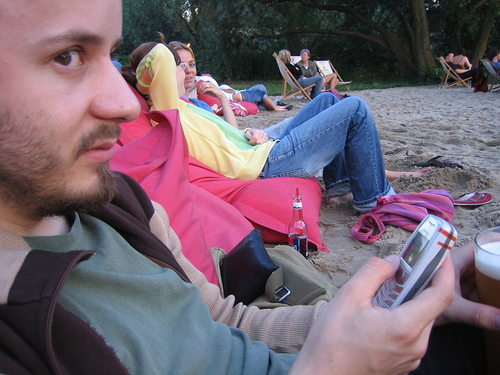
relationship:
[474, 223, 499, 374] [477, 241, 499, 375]
glass for drinking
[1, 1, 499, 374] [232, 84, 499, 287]
people are at beach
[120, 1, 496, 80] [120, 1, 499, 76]
trees are in a line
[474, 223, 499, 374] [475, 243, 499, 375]
glass has beer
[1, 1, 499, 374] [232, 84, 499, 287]
people are on beach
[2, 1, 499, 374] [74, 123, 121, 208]
man has a goatee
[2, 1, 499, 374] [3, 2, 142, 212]
man has a face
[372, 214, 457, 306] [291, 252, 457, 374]
cell phone in a hand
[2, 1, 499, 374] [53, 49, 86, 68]
man has an eye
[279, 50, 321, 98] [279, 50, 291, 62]
woman has a head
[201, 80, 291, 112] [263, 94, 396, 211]
person wearing jeans